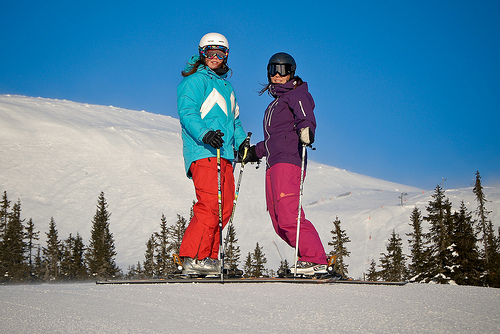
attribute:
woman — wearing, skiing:
[159, 22, 257, 290]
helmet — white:
[194, 22, 236, 62]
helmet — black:
[257, 49, 303, 83]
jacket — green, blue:
[175, 68, 238, 166]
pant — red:
[168, 151, 246, 263]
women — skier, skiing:
[145, 25, 333, 305]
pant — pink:
[246, 158, 337, 254]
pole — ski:
[198, 140, 237, 268]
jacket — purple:
[253, 81, 325, 170]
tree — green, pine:
[41, 204, 159, 279]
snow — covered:
[49, 112, 158, 198]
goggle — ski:
[183, 43, 235, 69]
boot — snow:
[159, 242, 249, 292]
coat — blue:
[151, 70, 251, 195]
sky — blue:
[115, 19, 178, 78]